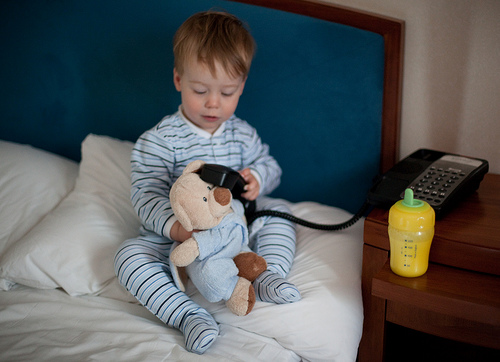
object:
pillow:
[4, 141, 78, 255]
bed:
[2, 142, 371, 359]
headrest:
[0, 132, 124, 300]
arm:
[170, 228, 216, 267]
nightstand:
[360, 166, 499, 356]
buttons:
[421, 188, 430, 194]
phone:
[363, 145, 492, 217]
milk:
[391, 240, 430, 277]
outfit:
[188, 189, 245, 304]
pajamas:
[115, 110, 304, 356]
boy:
[116, 5, 305, 349]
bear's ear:
[182, 160, 202, 175]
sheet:
[3, 296, 132, 359]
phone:
[193, 163, 258, 229]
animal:
[170, 159, 267, 316]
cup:
[388, 189, 434, 276]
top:
[400, 189, 420, 207]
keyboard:
[413, 156, 483, 212]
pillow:
[0, 133, 363, 360]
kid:
[112, 9, 297, 360]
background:
[1, 0, 140, 127]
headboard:
[2, 4, 404, 156]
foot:
[226, 275, 255, 318]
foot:
[234, 251, 268, 278]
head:
[173, 5, 253, 124]